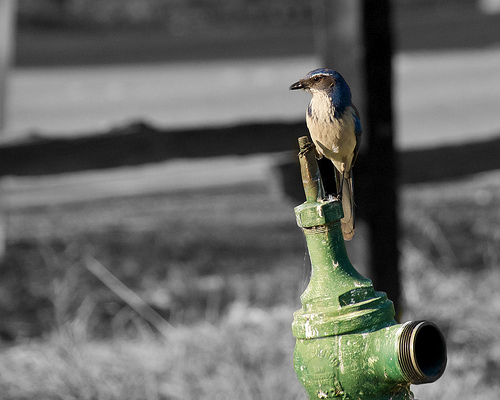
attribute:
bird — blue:
[279, 60, 374, 250]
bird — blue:
[287, 67, 365, 244]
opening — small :
[411, 319, 448, 384]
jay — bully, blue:
[289, 65, 361, 236]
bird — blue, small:
[287, 67, 366, 201]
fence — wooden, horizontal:
[41, 112, 295, 172]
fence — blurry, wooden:
[1, 0, 498, 325]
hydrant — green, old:
[291, 133, 448, 398]